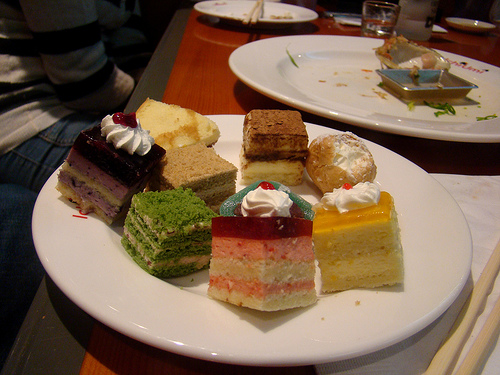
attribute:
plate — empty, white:
[258, 39, 498, 133]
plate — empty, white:
[202, 2, 322, 24]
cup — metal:
[392, 68, 475, 98]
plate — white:
[381, 135, 498, 333]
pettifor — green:
[117, 181, 222, 284]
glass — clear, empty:
[351, 9, 402, 36]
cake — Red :
[207, 215, 318, 315]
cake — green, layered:
[113, 189, 220, 282]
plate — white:
[23, 99, 483, 366]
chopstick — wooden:
[422, 238, 498, 372]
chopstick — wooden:
[453, 290, 499, 374]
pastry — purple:
[55, 108, 167, 223]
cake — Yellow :
[308, 182, 410, 292]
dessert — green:
[115, 178, 221, 284]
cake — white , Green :
[178, 147, 383, 295]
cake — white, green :
[149, 193, 269, 297]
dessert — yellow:
[348, 207, 390, 283]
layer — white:
[204, 289, 320, 310]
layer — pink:
[206, 270, 317, 293]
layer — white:
[206, 251, 319, 282]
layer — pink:
[206, 234, 314, 257]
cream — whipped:
[100, 114, 152, 155]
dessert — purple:
[57, 107, 163, 227]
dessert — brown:
[306, 132, 386, 199]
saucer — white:
[450, 14, 484, 37]